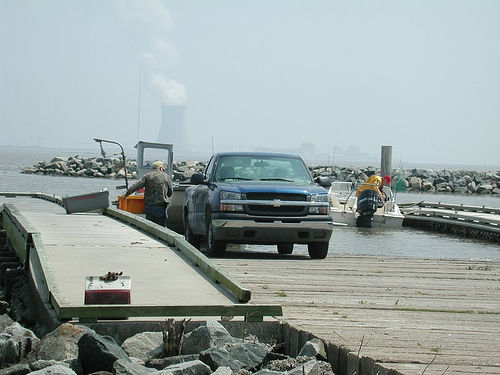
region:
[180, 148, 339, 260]
blue chevy pick up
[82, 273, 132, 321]
red and white ice chest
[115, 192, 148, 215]
orange plastic tote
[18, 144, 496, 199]
jetty made of rocks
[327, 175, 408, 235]
small boat in the water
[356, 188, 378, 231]
engine of small boat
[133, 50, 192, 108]
steam coming from a power plant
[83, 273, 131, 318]
red cooler with white top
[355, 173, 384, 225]
person in yellow rain coat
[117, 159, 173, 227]
man carrying orange container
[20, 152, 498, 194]
row of large grey rocks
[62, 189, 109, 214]
large grey plastic container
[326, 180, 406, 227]
small white boat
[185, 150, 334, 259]
blue Chevy pickup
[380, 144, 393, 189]
short wood pole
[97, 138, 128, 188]
bent pole with cherry picker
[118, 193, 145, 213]
orange container man is carrying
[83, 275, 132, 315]
the red and white cooler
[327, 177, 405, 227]
the white boat on the water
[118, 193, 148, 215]
the orange box shaped container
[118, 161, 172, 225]
the man holding the orange container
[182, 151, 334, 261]
the blue truck near the water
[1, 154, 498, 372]
the large rocks near the water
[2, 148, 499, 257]
the water near the large rocks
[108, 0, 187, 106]
the smoke in the distance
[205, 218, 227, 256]
the wheel under the truck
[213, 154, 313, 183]
the windshield on the truck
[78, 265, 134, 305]
small pink and white box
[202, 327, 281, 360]
gray rocks in the enclosure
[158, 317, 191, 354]
small tree stump in the enclosure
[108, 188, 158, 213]
orange container in man's hand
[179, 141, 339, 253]
blue truck parked on dock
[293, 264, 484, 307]
wooden section on the docks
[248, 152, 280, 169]
mirror in front of truck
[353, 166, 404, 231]
man standing on boat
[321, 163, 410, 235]
white boat in the water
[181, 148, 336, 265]
a pickup truck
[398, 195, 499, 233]
the narrow dock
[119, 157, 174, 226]
a man on right side of the truck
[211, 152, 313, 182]
the windshield of truck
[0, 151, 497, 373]
the grey boulders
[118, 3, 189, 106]
the thick smoke in the air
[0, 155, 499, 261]
the waters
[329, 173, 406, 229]
the small white boat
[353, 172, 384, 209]
the gold coat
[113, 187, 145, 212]
the orange crane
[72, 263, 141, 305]
large pink and white box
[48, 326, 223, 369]
cluster of large gray stones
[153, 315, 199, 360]
small tree stalks in rocks